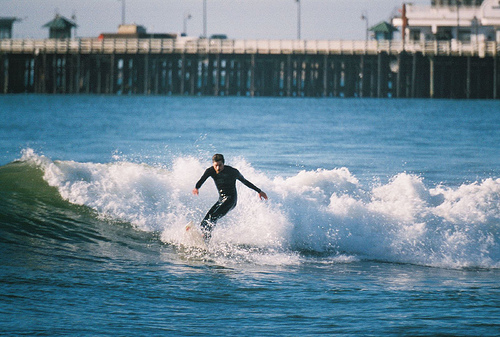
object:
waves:
[158, 207, 414, 296]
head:
[211, 154, 225, 172]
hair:
[212, 153, 225, 165]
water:
[0, 92, 499, 336]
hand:
[258, 191, 268, 201]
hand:
[191, 188, 199, 197]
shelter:
[390, 0, 500, 40]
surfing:
[0, 149, 499, 283]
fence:
[0, 40, 500, 57]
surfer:
[193, 153, 269, 245]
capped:
[3, 186, 483, 319]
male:
[191, 153, 270, 246]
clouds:
[160, 0, 324, 37]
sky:
[0, 0, 428, 40]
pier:
[1, 38, 138, 52]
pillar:
[0, 50, 499, 100]